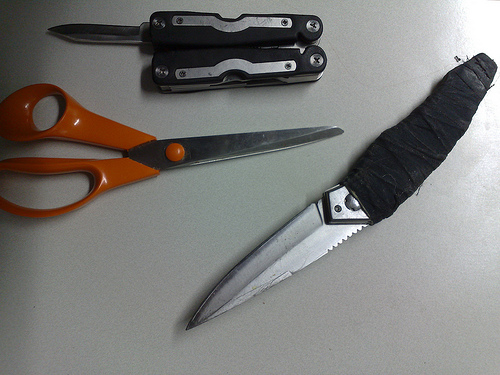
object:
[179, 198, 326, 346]
blade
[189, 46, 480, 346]
knife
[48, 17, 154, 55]
blade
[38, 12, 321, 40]
knife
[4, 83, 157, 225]
handle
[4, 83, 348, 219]
scissors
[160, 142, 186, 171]
swivel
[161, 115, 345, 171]
blade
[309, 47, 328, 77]
screw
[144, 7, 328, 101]
multitool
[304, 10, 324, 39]
screw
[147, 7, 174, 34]
screw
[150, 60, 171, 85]
screw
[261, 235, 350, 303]
edge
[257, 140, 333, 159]
edge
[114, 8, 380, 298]
tools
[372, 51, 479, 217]
handle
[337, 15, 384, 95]
table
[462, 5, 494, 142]
light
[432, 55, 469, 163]
tape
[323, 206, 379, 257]
serrated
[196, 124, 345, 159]
blades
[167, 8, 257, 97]
handle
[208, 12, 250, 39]
silver